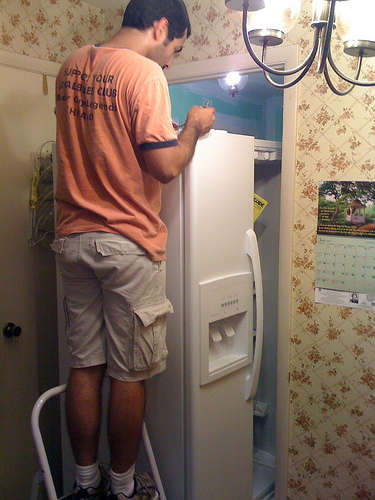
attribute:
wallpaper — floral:
[294, 78, 372, 490]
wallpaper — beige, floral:
[3, 2, 374, 497]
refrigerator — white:
[46, 133, 264, 487]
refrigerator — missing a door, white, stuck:
[53, 127, 274, 494]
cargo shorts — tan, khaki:
[47, 227, 177, 378]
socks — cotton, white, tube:
[71, 457, 123, 498]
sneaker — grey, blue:
[112, 471, 150, 498]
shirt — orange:
[18, 26, 206, 268]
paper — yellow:
[255, 191, 267, 221]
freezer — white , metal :
[112, 138, 299, 460]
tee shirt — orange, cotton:
[48, 40, 186, 265]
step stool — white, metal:
[27, 382, 170, 499]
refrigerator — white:
[29, 128, 281, 496]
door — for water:
[164, 124, 270, 499]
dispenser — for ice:
[208, 308, 247, 366]